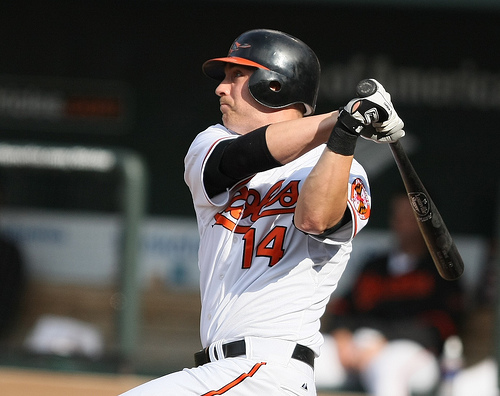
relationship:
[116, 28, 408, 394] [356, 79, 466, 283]
batter holding bat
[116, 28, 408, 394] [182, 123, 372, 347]
batter has top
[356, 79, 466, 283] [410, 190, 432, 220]
bat has sticker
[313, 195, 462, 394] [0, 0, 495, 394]
man sitting in dugout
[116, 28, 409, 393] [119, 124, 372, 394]
player has uniform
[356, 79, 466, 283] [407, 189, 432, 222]
bat has writing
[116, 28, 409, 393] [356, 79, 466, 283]
player swinging bat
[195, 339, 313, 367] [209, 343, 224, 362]
belt has loop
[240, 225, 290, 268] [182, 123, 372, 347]
number on top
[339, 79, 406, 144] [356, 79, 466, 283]
hands gripping bat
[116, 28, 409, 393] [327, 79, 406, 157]
player has gloves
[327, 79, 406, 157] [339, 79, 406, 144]
gloves on hands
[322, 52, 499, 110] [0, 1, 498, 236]
name on stadium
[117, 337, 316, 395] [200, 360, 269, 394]
pants have stipe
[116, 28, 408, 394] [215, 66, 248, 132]
batter making face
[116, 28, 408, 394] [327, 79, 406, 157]
batter wearing gloves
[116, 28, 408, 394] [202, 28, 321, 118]
batter has helmet